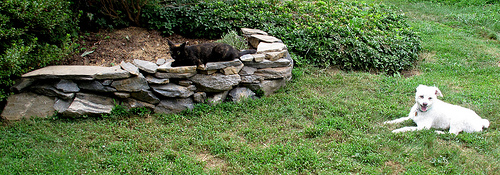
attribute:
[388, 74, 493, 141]
dog — white, sitting, happy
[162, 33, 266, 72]
cat — black, resting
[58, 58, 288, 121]
rocks — piled, gray